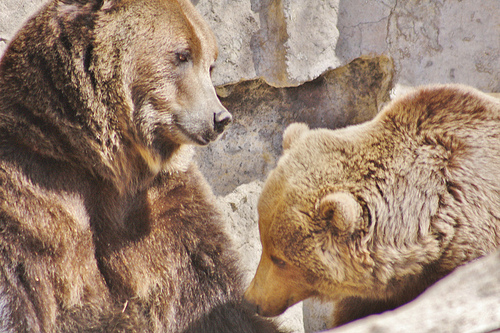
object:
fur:
[19, 181, 77, 328]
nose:
[240, 293, 262, 313]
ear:
[311, 188, 363, 240]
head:
[79, 0, 236, 148]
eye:
[269, 248, 285, 269]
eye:
[169, 44, 195, 66]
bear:
[239, 80, 500, 329]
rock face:
[327, 246, 500, 332]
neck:
[340, 114, 447, 296]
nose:
[212, 108, 232, 130]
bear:
[0, 0, 295, 333]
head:
[239, 120, 390, 320]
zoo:
[0, 0, 499, 333]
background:
[0, 0, 499, 332]